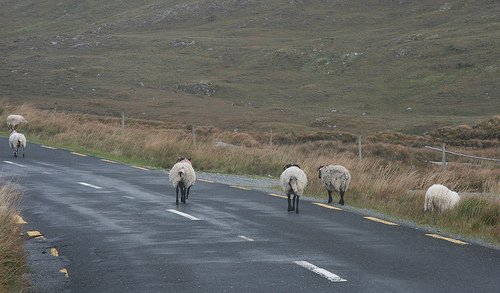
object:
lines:
[310, 202, 471, 246]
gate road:
[338, 173, 498, 198]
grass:
[232, 79, 282, 107]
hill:
[245, 24, 356, 74]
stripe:
[77, 181, 102, 189]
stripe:
[238, 235, 255, 242]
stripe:
[293, 260, 348, 283]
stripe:
[50, 247, 59, 256]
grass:
[356, 150, 420, 210]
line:
[165, 208, 201, 221]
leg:
[180, 188, 184, 202]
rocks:
[180, 81, 221, 94]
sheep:
[280, 163, 308, 214]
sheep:
[9, 129, 27, 158]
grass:
[416, 0, 499, 78]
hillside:
[1, 0, 498, 136]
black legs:
[293, 195, 300, 214]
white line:
[3, 161, 24, 168]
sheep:
[169, 157, 197, 205]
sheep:
[423, 183, 462, 212]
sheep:
[317, 164, 351, 205]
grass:
[127, 136, 169, 158]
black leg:
[287, 194, 292, 212]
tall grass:
[355, 163, 410, 206]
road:
[26, 211, 391, 290]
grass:
[296, 85, 361, 115]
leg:
[175, 185, 179, 205]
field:
[62, 63, 143, 100]